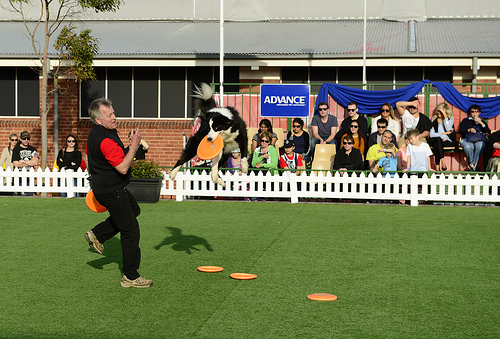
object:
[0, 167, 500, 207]
fence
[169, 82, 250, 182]
dog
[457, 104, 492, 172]
people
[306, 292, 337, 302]
frisbees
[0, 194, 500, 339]
ground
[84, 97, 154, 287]
man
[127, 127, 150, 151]
crossed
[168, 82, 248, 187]
jumping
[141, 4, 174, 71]
air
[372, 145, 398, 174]
boy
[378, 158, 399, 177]
shirt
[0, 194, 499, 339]
grass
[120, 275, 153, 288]
shoe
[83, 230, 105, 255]
foot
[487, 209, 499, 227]
edge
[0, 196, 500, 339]
field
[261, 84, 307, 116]
sign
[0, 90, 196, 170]
wall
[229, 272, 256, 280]
frisbees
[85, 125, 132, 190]
vest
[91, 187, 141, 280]
jeans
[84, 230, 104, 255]
shoe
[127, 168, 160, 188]
planter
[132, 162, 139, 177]
flowers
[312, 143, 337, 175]
chair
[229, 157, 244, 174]
coat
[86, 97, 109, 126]
hair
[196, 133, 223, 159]
flying disc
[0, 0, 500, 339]
background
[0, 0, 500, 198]
building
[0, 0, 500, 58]
roof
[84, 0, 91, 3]
leaves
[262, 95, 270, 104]
word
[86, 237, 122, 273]
shadow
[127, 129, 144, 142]
holding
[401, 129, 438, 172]
people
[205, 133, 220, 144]
mouth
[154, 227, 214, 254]
shadow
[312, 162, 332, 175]
seat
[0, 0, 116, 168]
tree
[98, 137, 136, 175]
arms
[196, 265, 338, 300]
three